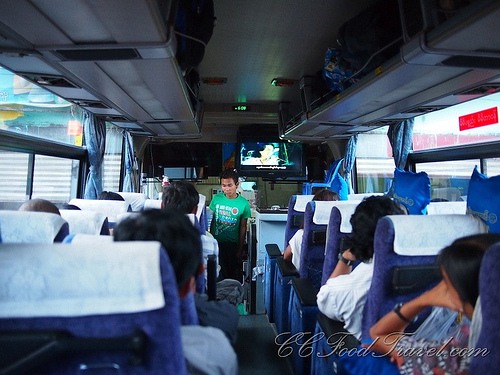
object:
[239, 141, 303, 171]
television screen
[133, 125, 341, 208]
front of vehicle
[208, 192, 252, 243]
green shirt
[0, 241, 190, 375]
blue seat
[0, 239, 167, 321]
white cloth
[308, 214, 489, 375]
blue seat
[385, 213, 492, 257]
white cloth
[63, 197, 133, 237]
seat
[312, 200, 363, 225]
white cloth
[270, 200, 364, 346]
blue seat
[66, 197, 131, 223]
cloth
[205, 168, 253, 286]
man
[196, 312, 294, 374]
aisle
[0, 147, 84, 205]
window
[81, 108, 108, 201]
curtains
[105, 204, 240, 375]
man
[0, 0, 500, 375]
bus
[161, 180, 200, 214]
hair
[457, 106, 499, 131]
sticker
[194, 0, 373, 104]
ceiling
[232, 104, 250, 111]
light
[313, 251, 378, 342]
shirt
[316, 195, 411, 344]
people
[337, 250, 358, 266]
watch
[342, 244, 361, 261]
mans hand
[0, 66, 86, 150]
open windows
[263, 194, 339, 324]
chairs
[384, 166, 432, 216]
pillows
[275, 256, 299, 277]
armrest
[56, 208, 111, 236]
seats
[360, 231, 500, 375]
woman